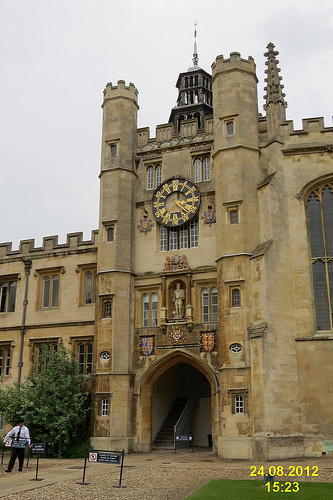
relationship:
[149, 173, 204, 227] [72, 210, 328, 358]
clock on building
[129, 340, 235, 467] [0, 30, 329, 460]
entrance to building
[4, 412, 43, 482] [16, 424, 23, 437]
man wears tie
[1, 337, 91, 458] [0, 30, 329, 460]
tree next building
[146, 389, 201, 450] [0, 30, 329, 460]
stairs in building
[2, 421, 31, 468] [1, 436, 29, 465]
man behind sign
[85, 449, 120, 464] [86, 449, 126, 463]
sign shows forbidden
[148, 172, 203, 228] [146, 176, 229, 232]
roman numerals on clock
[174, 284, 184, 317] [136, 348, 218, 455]
statue above entrance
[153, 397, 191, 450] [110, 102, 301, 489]
stairs on building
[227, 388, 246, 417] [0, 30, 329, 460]
window at building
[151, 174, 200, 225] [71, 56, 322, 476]
clock on building